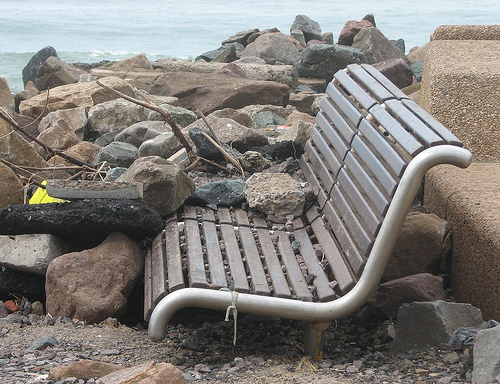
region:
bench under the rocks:
[152, 61, 467, 358]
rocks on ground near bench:
[335, 338, 448, 377]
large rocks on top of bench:
[38, 41, 299, 191]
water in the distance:
[4, 3, 464, 30]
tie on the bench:
[215, 290, 256, 342]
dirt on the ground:
[33, 327, 140, 349]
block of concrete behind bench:
[423, 27, 498, 290]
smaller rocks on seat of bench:
[281, 226, 341, 303]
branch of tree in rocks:
[103, 73, 206, 160]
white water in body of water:
[103, 41, 171, 61]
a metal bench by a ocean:
[143, 61, 462, 351]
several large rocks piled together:
[85, 14, 380, 216]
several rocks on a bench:
[190, 64, 363, 288]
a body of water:
[7, 6, 220, 55]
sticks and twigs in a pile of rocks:
[22, 90, 188, 205]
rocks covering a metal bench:
[155, 57, 356, 348]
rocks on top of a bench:
[110, 47, 406, 323]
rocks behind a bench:
[366, 224, 469, 381]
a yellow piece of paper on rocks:
[20, 172, 83, 220]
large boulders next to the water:
[122, 18, 386, 114]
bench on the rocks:
[104, 63, 474, 370]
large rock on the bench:
[239, 160, 310, 221]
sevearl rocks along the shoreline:
[2, 13, 424, 327]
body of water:
[0, 3, 497, 80]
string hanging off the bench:
[221, 291, 243, 338]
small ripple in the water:
[3, 46, 157, 63]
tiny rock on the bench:
[289, 233, 301, 254]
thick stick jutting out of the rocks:
[93, 71, 197, 148]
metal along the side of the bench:
[111, 126, 486, 338]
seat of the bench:
[165, 192, 345, 304]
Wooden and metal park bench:
[142, 62, 473, 355]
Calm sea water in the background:
[1, 1, 497, 93]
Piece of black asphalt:
[1, 199, 166, 232]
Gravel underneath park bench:
[1, 310, 472, 382]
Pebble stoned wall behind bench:
[420, 24, 498, 320]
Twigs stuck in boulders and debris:
[0, 76, 246, 201]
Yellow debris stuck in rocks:
[25, 179, 69, 204]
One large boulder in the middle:
[150, 74, 289, 113]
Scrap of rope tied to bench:
[224, 289, 241, 346]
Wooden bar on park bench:
[185, 220, 207, 285]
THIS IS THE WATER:
[0, 0, 497, 95]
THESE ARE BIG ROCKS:
[0, 10, 498, 380]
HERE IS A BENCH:
[141, 58, 473, 343]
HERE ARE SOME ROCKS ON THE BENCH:
[0, 155, 310, 231]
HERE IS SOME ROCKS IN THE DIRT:
[0, 312, 498, 382]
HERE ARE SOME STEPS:
[421, 23, 496, 317]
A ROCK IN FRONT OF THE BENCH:
[43, 232, 180, 325]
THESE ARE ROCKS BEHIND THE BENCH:
[367, 270, 497, 380]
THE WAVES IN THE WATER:
[2, 44, 192, 91]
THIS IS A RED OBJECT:
[2, 296, 21, 312]